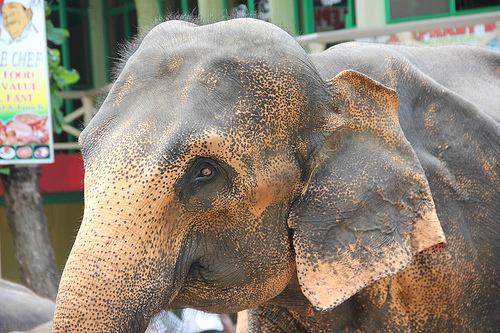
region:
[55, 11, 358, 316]
head of an elephant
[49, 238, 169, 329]
nose of an elephant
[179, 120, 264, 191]
an eye of an elephant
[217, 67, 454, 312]
ear of an elephant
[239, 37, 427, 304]
an ear of an elephant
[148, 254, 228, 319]
mouth of an elephant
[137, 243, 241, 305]
a mouth of an elephant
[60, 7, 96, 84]
window of a building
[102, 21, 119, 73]
window of a building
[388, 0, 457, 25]
window of a building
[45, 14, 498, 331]
Grey elephant with light colored patches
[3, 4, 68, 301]
Sign on slender tree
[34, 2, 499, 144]
Building with green frames around windows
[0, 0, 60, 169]
Sign with the words Chef, Food, Value and Fast visable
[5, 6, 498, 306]
Building with white railing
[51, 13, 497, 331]
Elephant with side of face and one ear visable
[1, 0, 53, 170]
White sign with picture of man in chef hat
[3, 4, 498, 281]
Green, white and red building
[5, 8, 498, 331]
Elephant standing in front of building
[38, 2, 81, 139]
Dark and light green plant leaves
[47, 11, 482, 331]
An elephant in a city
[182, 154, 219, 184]
yellow eye of a gray elephant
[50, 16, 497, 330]
gray and yellow spotted elephant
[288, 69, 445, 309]
gray and yellow spotted elephant ear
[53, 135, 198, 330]
gray and yellow spotted elephant trunk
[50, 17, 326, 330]
gray and yellow spotted elephant head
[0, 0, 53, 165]
red, yellow, green, and white sign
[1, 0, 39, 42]
drawing of male chef in white hat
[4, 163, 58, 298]
brown tree trunk with bark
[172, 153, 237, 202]
gray and yellow spotted elephant eye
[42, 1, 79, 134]
bright green tree leaves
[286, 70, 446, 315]
An older asian elephant with typically smaller ears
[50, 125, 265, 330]
Asian elephants often get "white" patches as they get older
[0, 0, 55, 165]
A poster for a restaurant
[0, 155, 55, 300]
a trunk of a tree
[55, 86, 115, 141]
a railing is in the background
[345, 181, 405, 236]
veins rise up and are visible on the ear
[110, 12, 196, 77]
short stubbly hair on the head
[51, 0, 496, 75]
the bright green trim on the building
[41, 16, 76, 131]
green leaves from the tree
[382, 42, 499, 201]
ridges show on this elephant's back